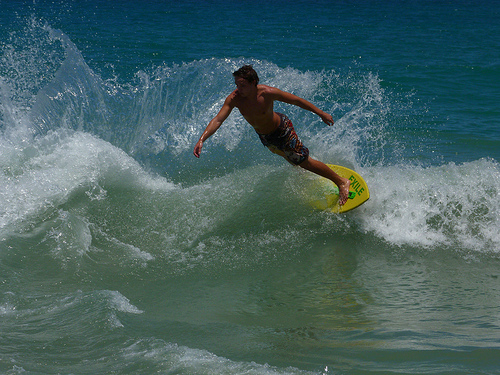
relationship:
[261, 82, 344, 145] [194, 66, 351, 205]
arm on man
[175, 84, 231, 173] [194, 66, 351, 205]
arm on man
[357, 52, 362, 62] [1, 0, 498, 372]
drop of ocean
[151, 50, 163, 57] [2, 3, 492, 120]
water drop in air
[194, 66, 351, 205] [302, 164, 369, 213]
man on surf board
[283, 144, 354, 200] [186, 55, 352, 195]
legs of man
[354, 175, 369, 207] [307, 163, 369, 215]
tip of surfboard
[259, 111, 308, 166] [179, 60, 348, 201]
swimming trunks worn by surfer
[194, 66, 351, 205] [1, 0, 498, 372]
man surf boarding in ocean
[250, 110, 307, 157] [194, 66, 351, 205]
swimming trunks of man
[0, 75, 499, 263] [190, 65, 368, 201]
wave ridden by surfer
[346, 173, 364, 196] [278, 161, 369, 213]
decal on surf board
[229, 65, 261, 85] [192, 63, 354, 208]
brown hair of surfer